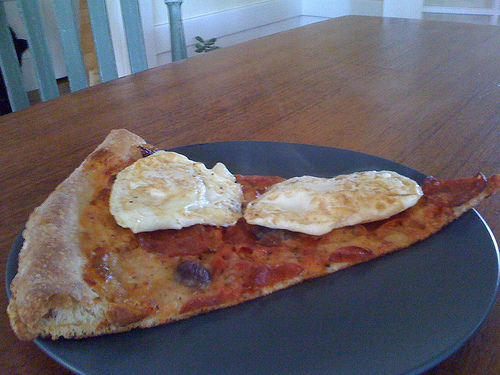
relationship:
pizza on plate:
[15, 126, 498, 343] [4, 135, 498, 374]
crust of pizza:
[6, 126, 129, 345] [15, 126, 498, 343]